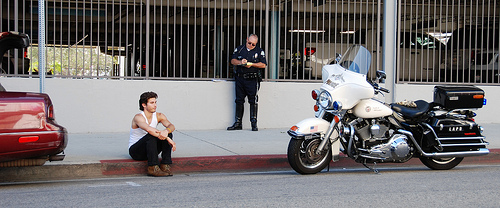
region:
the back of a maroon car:
[0, 79, 69, 171]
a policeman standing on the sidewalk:
[227, 30, 267, 133]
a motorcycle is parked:
[280, 41, 490, 172]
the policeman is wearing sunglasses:
[225, 30, 266, 130]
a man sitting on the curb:
[127, 89, 175, 179]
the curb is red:
[98, 145, 499, 175]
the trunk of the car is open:
[1, 22, 71, 172]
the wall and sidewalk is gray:
[2, 75, 499, 157]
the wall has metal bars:
[1, 0, 498, 89]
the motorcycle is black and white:
[280, 38, 490, 177]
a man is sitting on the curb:
[118, 88, 181, 179]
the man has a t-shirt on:
[126, 109, 160, 151]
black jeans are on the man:
[127, 132, 174, 166]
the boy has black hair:
[137, 89, 157, 109]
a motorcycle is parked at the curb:
[288, 40, 491, 172]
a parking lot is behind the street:
[8, 5, 493, 180]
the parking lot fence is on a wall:
[6, 1, 497, 82]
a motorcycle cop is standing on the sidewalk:
[223, 30, 272, 133]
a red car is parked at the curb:
[3, 25, 68, 187]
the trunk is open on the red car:
[0, 29, 66, 165]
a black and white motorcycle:
[285, 45, 489, 175]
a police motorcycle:
[285, 40, 490, 176]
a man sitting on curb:
[125, 89, 172, 176]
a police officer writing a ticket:
[226, 33, 266, 132]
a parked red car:
[0, 77, 66, 171]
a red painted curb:
[98, 147, 495, 179]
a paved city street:
[3, 159, 498, 204]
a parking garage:
[2, 0, 498, 128]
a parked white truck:
[295, 26, 437, 79]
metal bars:
[5, 0, 497, 79]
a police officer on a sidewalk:
[226, 33, 268, 133]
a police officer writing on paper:
[227, 33, 267, 131]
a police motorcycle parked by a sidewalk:
[286, 40, 491, 173]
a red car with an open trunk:
[0, 29, 68, 167]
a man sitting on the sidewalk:
[127, 89, 176, 176]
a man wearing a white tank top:
[128, 90, 178, 177]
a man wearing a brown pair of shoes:
[128, 88, 175, 178]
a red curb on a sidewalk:
[99, 153, 499, 176]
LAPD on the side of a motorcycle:
[446, 125, 464, 132]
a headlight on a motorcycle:
[314, 89, 336, 113]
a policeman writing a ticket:
[231, 30, 266, 132]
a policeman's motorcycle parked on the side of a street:
[290, 43, 490, 174]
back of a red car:
[1, 83, 67, 170]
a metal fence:
[3, 3, 496, 80]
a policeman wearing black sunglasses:
[243, 38, 257, 48]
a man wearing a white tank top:
[129, 110, 160, 149]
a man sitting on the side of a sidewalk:
[127, 91, 174, 176]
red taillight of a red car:
[46, 102, 56, 121]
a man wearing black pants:
[128, 128, 174, 164]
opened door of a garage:
[29, 47, 129, 78]